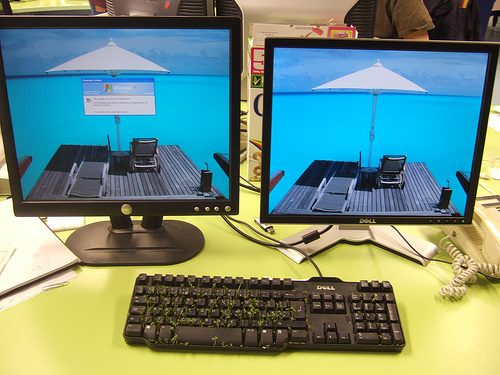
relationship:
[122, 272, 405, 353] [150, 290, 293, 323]
keyboard growing greenery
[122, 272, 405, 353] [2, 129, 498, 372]
keyboard on desk